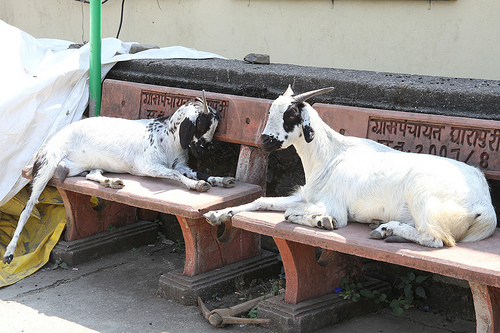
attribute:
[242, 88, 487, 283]
goat — black, white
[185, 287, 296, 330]
axe — laying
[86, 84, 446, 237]
goats — sitting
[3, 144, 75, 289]
tarp — yellow, lying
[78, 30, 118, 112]
pole — green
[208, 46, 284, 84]
rock — grey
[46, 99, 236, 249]
goat — black, white, stretching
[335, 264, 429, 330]
weeds — under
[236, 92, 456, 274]
goats — small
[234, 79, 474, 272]
goats — small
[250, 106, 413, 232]
goat — small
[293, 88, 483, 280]
goat — small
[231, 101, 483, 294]
goat — small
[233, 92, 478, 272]
goat — small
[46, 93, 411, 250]
goats — sitting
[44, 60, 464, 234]
goats — white, black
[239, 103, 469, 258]
goats — black, white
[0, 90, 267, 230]
goats — spotted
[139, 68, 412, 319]
bench — red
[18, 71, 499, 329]
bench — red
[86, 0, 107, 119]
pole — light, green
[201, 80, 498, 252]
goat — white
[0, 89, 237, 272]
goat — white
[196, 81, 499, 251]
animal — sitting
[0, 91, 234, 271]
animal — sitting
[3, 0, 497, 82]
wall — white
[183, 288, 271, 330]
ax — pick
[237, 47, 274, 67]
rock — small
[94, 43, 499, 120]
wall — brick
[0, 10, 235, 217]
tarp — white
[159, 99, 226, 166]
face — white, black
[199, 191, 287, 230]
leg — four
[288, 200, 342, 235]
leg — four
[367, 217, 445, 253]
leg — four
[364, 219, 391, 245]
leg — four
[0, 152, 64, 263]
leg — extended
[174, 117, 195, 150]
spots — black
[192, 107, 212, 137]
spots — black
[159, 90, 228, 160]
head — cabro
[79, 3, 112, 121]
bar — vertical, green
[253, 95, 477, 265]
goat — BLACK, WHITE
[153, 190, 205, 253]
bench — BLACK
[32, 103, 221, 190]
goat — WHITE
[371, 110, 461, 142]
bench — STONE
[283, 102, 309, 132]
eye — BLACK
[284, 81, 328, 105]
horns — GOAT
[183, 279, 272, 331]
axe — PICK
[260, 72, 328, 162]
head — GOATS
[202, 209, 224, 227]
hoof — GOATS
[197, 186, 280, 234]
leg — STRAIGHTENED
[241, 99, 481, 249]
goat — WHITE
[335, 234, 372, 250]
bench — BROWN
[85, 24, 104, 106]
pole — GREEN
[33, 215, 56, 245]
tarp — YELLOW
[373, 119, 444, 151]
writing — ARABIC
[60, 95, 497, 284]
bench — RED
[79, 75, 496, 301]
bench — RED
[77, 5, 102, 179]
pole — GREEN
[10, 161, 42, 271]
leg — BACK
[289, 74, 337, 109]
horn — LONG